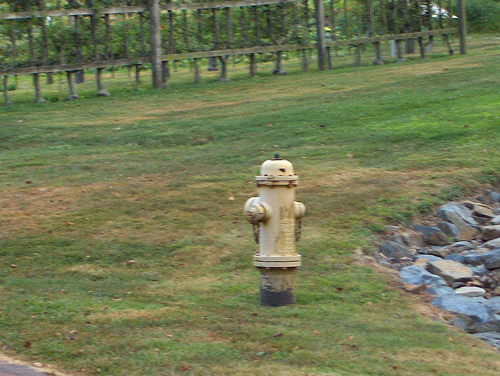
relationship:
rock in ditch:
[410, 258, 443, 293] [379, 203, 493, 363]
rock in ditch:
[456, 291, 496, 327] [379, 203, 493, 363]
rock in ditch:
[446, 196, 480, 230] [379, 203, 493, 363]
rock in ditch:
[429, 259, 472, 282] [379, 203, 493, 363]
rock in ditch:
[479, 247, 498, 265] [379, 203, 493, 363]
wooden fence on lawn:
[4, 4, 496, 91] [323, 99, 470, 162]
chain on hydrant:
[292, 217, 303, 245] [240, 160, 320, 304]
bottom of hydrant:
[253, 260, 300, 306] [244, 150, 309, 303]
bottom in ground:
[253, 260, 300, 306] [2, 36, 497, 373]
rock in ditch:
[431, 291, 495, 327] [397, 153, 499, 339]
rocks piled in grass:
[421, 222, 469, 258] [0, 32, 498, 374]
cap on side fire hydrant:
[242, 200, 272, 225] [237, 147, 312, 310]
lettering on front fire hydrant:
[277, 204, 299, 253] [241, 150, 307, 305]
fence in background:
[2, 27, 466, 104] [2, 0, 499, 105]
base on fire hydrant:
[243, 261, 304, 308] [237, 147, 312, 310]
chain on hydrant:
[248, 221, 261, 242] [244, 150, 309, 303]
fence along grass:
[6, 22, 481, 90] [27, 109, 487, 189]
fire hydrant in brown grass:
[241, 150, 307, 305] [3, 187, 183, 248]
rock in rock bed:
[429, 259, 472, 282] [366, 185, 499, 353]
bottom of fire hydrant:
[254, 260, 300, 306] [251, 245, 311, 312]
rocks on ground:
[421, 222, 459, 244] [2, 36, 497, 373]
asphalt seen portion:
[12, 343, 56, 374] [21, 357, 33, 366]